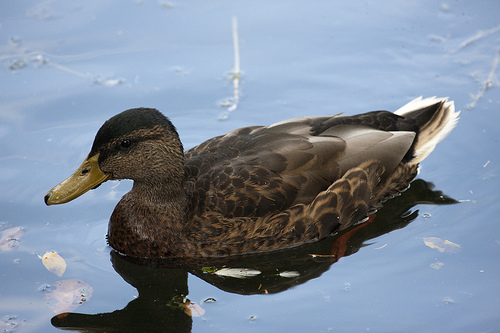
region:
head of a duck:
[31, 90, 195, 240]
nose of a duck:
[80, 161, 105, 176]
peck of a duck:
[22, 175, 105, 216]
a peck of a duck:
[40, 168, 124, 208]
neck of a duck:
[115, 120, 227, 187]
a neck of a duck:
[117, 163, 197, 195]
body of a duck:
[135, 116, 331, 241]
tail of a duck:
[363, 67, 470, 205]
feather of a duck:
[264, 90, 433, 212]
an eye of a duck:
[102, 123, 139, 165]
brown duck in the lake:
[43, 90, 460, 262]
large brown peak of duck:
[44, 149, 108, 206]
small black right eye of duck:
[123, 137, 133, 152]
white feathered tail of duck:
[389, 90, 459, 163]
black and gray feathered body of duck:
[281, 101, 438, 169]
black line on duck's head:
[86, 105, 185, 160]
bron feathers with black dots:
[109, 127, 411, 259]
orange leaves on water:
[0, 26, 495, 331]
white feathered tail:
[394, 94, 457, 163]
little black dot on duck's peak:
[79, 167, 88, 178]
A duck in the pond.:
[47, 25, 469, 311]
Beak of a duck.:
[38, 147, 117, 222]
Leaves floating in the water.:
[41, 243, 98, 316]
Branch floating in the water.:
[217, 3, 246, 129]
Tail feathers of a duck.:
[372, 88, 475, 175]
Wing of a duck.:
[255, 160, 403, 265]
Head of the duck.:
[75, 93, 183, 209]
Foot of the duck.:
[312, 205, 406, 265]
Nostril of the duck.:
[80, 162, 96, 181]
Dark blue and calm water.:
[289, 18, 359, 94]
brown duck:
[35, 88, 454, 273]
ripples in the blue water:
[277, 23, 337, 61]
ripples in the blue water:
[403, 257, 434, 278]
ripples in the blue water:
[344, 257, 384, 305]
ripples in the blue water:
[317, 63, 335, 80]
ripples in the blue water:
[359, 20, 412, 60]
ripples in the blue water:
[307, 32, 335, 49]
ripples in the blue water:
[161, 50, 212, 85]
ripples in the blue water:
[29, 17, 96, 68]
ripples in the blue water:
[136, 45, 195, 81]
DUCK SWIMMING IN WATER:
[38, 90, 465, 264]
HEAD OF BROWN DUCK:
[42, 100, 192, 219]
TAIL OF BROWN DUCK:
[383, 85, 465, 160]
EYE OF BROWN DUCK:
[111, 140, 136, 159]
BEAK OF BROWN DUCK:
[39, 153, 107, 213]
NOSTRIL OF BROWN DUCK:
[71, 165, 91, 179]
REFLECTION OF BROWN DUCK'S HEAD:
[45, 268, 202, 330]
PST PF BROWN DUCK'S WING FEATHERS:
[199, 143, 413, 246]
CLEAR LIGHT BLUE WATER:
[161, 46, 218, 81]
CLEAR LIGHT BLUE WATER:
[343, 298, 405, 331]